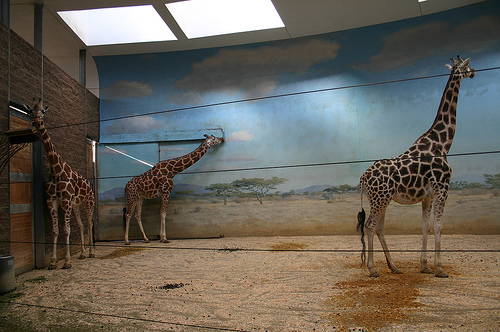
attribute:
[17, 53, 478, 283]
giraffes — inside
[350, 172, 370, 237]
tail — long, brown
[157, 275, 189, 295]
poop — piled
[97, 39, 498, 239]
backdrop — fake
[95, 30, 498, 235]
wall — painted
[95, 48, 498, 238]
mural — safari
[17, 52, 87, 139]
wall — brick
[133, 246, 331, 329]
dirt — tan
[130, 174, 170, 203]
coat — spotted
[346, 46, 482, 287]
giraffe — biggest, brown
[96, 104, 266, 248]
giraffe — brown, center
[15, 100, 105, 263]
giraffe — brown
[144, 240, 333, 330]
dirt — brown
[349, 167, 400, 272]
legs — back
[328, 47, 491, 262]
giraffe — big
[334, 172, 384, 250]
tail — long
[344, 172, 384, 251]
turf — black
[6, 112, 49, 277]
door — orange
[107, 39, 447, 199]
sky — blue, painted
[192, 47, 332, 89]
clouds — painted, white